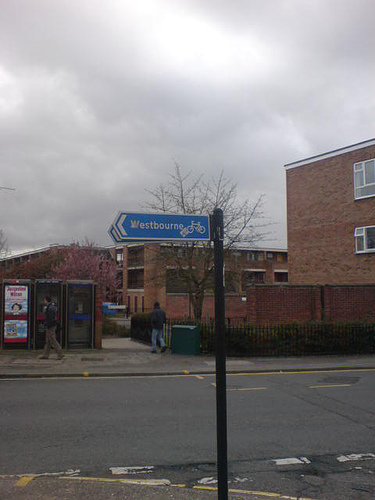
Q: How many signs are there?
A: One.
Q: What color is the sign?
A: Blue.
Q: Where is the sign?
A: On the street.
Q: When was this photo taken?
A: During the day.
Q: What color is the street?
A: Gray.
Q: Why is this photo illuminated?
A: Sunlight.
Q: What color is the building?
A: Brown.